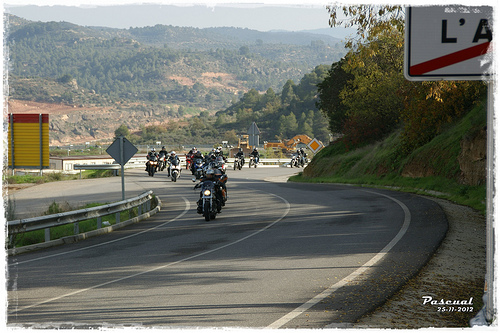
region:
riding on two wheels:
[135, 133, 325, 235]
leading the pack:
[120, 128, 335, 235]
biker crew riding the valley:
[118, 101, 333, 237]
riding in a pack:
[97, 76, 337, 276]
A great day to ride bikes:
[95, 105, 371, 250]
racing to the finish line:
[75, 61, 380, 277]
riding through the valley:
[60, 25, 388, 283]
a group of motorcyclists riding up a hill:
[142, 137, 312, 228]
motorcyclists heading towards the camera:
[136, 140, 306, 220]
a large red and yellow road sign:
[7, 110, 54, 179]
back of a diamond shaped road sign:
[103, 131, 138, 201]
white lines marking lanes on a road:
[6, 178, 433, 328]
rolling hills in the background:
[7, 10, 364, 67]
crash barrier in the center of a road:
[8, 189, 160, 265]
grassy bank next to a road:
[289, 88, 489, 218]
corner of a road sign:
[401, 8, 493, 81]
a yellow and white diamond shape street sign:
[305, 133, 323, 154]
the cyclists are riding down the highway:
[123, 119, 435, 307]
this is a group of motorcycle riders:
[139, 121, 346, 234]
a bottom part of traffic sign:
[378, 8, 490, 99]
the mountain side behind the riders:
[39, 14, 322, 114]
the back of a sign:
[97, 109, 143, 176]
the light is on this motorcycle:
[185, 172, 240, 222]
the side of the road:
[327, 151, 489, 331]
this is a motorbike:
[185, 159, 237, 225]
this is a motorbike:
[136, 137, 168, 182]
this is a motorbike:
[186, 150, 208, 179]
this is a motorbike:
[246, 140, 269, 182]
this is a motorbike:
[230, 130, 247, 177]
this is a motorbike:
[284, 145, 311, 177]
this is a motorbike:
[141, 139, 173, 186]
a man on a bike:
[229, 135, 249, 169]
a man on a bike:
[186, 157, 241, 221]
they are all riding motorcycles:
[142, 127, 338, 234]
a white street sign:
[388, 9, 494, 99]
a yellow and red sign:
[12, 104, 83, 186]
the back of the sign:
[9, 101, 81, 183]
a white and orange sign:
[296, 119, 332, 164]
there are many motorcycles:
[137, 131, 324, 237]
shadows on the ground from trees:
[0, 213, 455, 323]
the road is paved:
[21, 236, 443, 331]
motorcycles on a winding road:
[4, 99, 494, 329]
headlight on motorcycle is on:
[198, 187, 210, 197]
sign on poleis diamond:
[102, 135, 139, 169]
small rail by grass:
[9, 184, 159, 254]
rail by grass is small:
[8, 183, 159, 252]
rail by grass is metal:
[6, 182, 163, 255]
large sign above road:
[10, 106, 52, 176]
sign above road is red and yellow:
[9, 108, 52, 173]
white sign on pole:
[400, 8, 490, 84]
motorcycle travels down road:
[147, 150, 159, 175]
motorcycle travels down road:
[165, 150, 182, 184]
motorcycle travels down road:
[194, 165, 226, 220]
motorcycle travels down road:
[229, 147, 246, 171]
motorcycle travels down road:
[246, 143, 260, 168]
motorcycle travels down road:
[287, 146, 308, 168]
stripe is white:
[267, 179, 411, 327]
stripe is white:
[1, 183, 288, 321]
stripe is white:
[261, 173, 418, 331]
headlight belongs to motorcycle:
[204, 189, 211, 196]